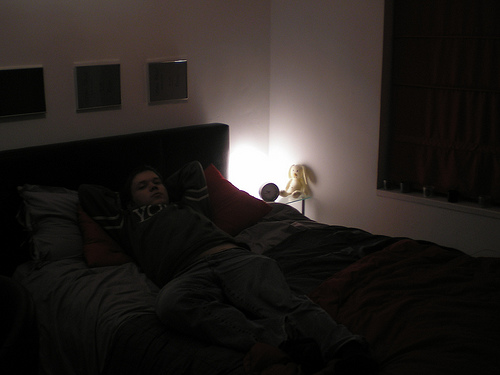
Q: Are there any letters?
A: Yes, there are letters.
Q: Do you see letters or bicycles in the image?
A: Yes, there are letters.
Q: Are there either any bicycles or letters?
A: Yes, there are letters.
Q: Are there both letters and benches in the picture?
A: No, there are letters but no benches.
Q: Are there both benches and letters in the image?
A: No, there are letters but no benches.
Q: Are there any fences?
A: No, there are no fences.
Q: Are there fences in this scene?
A: No, there are no fences.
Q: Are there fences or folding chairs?
A: No, there are no fences or folding chairs.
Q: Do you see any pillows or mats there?
A: Yes, there is a pillow.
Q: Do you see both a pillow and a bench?
A: No, there is a pillow but no benches.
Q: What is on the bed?
A: The pillow is on the bed.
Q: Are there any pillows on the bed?
A: Yes, there is a pillow on the bed.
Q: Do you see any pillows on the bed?
A: Yes, there is a pillow on the bed.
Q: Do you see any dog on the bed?
A: No, there is a pillow on the bed.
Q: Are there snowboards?
A: No, there are no snowboards.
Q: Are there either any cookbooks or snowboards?
A: No, there are no snowboards or cookbooks.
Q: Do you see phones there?
A: No, there are no phones.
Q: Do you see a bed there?
A: Yes, there is a bed.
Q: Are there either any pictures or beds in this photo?
A: Yes, there is a bed.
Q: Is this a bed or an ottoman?
A: This is a bed.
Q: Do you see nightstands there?
A: Yes, there is a nightstand.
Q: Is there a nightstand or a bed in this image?
A: Yes, there is a nightstand.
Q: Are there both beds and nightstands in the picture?
A: Yes, there are both a nightstand and a bed.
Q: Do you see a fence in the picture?
A: No, there are no fences.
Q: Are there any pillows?
A: Yes, there is a pillow.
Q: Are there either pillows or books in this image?
A: Yes, there is a pillow.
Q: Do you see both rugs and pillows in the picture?
A: No, there is a pillow but no rugs.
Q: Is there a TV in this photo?
A: No, there are no televisions.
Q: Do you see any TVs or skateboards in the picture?
A: No, there are no TVs or skateboards.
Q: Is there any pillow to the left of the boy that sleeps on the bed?
A: Yes, there is a pillow to the left of the boy.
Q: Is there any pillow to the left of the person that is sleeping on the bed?
A: Yes, there is a pillow to the left of the boy.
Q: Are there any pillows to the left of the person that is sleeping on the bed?
A: Yes, there is a pillow to the left of the boy.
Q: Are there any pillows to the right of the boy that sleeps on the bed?
A: No, the pillow is to the left of the boy.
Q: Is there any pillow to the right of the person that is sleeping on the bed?
A: No, the pillow is to the left of the boy.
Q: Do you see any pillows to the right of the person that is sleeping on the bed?
A: No, the pillow is to the left of the boy.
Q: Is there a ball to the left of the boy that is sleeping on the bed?
A: No, there is a pillow to the left of the boy.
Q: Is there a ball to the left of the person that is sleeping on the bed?
A: No, there is a pillow to the left of the boy.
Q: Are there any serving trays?
A: No, there are no serving trays.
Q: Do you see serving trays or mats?
A: No, there are no serving trays or mats.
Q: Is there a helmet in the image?
A: No, there are no helmets.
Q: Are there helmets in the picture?
A: No, there are no helmets.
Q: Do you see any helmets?
A: No, there are no helmets.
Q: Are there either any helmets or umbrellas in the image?
A: No, there are no helmets or umbrellas.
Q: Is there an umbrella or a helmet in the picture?
A: No, there are no helmets or umbrellas.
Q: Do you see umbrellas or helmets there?
A: No, there are no helmets or umbrellas.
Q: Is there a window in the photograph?
A: Yes, there is a window.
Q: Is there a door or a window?
A: Yes, there is a window.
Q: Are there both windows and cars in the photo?
A: No, there is a window but no cars.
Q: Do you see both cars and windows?
A: No, there is a window but no cars.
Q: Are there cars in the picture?
A: No, there are no cars.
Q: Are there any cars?
A: No, there are no cars.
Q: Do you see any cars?
A: No, there are no cars.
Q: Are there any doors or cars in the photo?
A: No, there are no cars or doors.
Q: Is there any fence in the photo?
A: No, there are no fences.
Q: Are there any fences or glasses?
A: No, there are no fences or glasses.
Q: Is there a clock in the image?
A: Yes, there is a clock.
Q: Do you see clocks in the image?
A: Yes, there is a clock.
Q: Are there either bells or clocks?
A: Yes, there is a clock.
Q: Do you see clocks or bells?
A: Yes, there is a clock.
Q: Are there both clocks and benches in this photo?
A: No, there is a clock but no benches.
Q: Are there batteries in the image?
A: No, there are no batteries.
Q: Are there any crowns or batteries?
A: No, there are no batteries or crowns.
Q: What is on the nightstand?
A: The clock is on the nightstand.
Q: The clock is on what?
A: The clock is on the nightstand.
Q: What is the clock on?
A: The clock is on the nightstand.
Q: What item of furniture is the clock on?
A: The clock is on the nightstand.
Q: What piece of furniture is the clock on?
A: The clock is on the nightstand.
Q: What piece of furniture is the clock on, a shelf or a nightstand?
A: The clock is on a nightstand.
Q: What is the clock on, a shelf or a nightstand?
A: The clock is on a nightstand.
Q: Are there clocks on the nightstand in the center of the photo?
A: Yes, there is a clock on the nightstand.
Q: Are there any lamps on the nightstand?
A: No, there is a clock on the nightstand.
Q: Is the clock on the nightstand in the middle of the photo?
A: Yes, the clock is on the nightstand.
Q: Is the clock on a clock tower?
A: No, the clock is on the nightstand.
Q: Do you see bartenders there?
A: No, there are no bartenders.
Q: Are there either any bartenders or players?
A: No, there are no bartenders or players.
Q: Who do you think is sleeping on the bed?
A: The boy is sleeping on the bed.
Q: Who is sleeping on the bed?
A: The boy is sleeping on the bed.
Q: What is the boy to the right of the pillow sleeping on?
A: The boy is sleeping on the bed.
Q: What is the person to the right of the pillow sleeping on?
A: The boy is sleeping on the bed.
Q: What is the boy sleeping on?
A: The boy is sleeping on the bed.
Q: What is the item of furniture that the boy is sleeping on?
A: The piece of furniture is a bed.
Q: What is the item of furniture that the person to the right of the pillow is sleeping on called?
A: The piece of furniture is a bed.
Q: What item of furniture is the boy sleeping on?
A: The boy is sleeping on the bed.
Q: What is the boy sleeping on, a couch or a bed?
A: The boy is sleeping on a bed.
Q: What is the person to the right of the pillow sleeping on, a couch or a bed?
A: The boy is sleeping on a bed.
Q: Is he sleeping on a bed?
A: Yes, the boy is sleeping on a bed.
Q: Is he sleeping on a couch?
A: No, the boy is sleeping on a bed.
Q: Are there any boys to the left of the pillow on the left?
A: No, the boy is to the right of the pillow.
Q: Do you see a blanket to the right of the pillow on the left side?
A: No, there is a boy to the right of the pillow.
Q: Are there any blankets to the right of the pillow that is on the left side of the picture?
A: No, there is a boy to the right of the pillow.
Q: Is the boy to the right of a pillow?
A: Yes, the boy is to the right of a pillow.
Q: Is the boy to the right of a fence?
A: No, the boy is to the right of a pillow.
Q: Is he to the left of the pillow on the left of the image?
A: No, the boy is to the right of the pillow.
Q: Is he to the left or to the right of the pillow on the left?
A: The boy is to the right of the pillow.